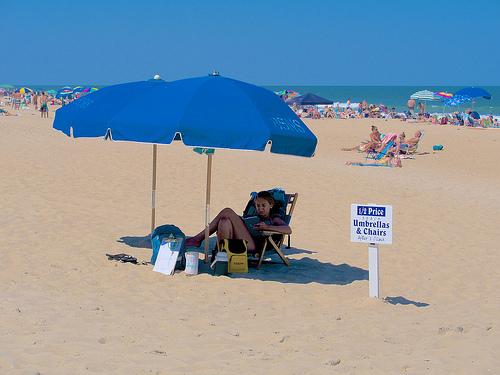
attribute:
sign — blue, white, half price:
[351, 203, 392, 244]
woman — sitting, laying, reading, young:
[183, 193, 292, 259]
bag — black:
[218, 239, 249, 271]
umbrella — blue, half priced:
[104, 72, 316, 157]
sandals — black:
[108, 252, 135, 264]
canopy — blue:
[102, 73, 317, 157]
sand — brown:
[3, 98, 499, 375]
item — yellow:
[221, 242, 248, 275]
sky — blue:
[2, 2, 497, 87]